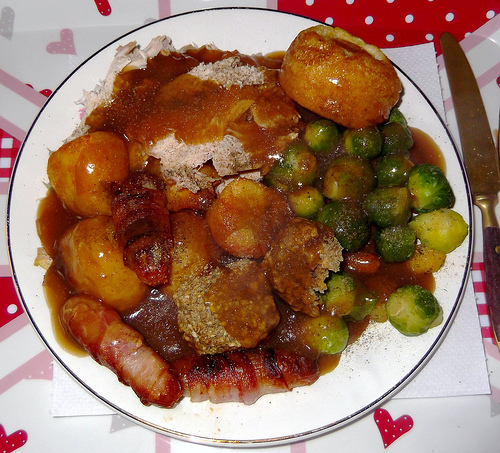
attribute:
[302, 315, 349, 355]
veggie — small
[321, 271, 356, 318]
green veggie — small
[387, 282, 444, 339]
brussel sprout — cooked, green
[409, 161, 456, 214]
brussel sprout — green, cooked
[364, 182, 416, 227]
brussel sprout — green, cooked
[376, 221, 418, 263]
brussel sprout — green, cooked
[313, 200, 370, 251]
brussel sprout — green, cooked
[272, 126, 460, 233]
brussels sprouts — cooked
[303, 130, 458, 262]
veggie — small, green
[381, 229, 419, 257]
veggie — green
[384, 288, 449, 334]
sprout — cooked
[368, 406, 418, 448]
heart — red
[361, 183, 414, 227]
vegetable — small, green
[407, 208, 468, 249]
brussel sprout — green, cooked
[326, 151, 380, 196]
brussel sprout — cooked, green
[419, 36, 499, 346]
knife — butter knife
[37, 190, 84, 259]
gravy — brown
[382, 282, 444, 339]
veggie — Small, green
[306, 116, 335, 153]
brussel sprout — cooked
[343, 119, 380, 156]
brussel sprout — cooked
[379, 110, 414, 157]
brussel sprout — cooked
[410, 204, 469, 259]
brussel sprout — cooked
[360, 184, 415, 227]
brussel sprout — cooked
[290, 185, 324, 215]
brussel sprout —  cooked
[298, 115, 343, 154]
veggie — small, green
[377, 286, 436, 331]
brussel sprout — green, cooked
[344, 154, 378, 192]
veggie — small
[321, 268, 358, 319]
brussel sprout — cooked, green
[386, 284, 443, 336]
veggie — green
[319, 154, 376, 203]
veggie — green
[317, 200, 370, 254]
veggie — green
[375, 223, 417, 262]
veggie — green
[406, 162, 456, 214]
veggie — green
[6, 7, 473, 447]
plate — green, white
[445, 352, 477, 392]
napkin — white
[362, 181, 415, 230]
brussel sprout — cooked, green